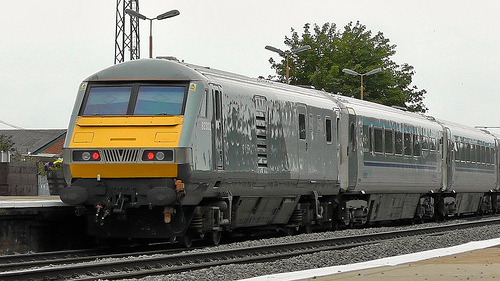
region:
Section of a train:
[53, 50, 221, 252]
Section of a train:
[194, 50, 309, 266]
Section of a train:
[261, 48, 347, 255]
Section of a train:
[272, 47, 362, 245]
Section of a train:
[314, 59, 397, 252]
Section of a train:
[347, 46, 413, 259]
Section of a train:
[392, 86, 452, 248]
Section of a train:
[335, 53, 414, 245]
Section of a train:
[445, 104, 489, 269]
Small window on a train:
[87, 75, 119, 120]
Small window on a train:
[131, 78, 186, 130]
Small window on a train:
[290, 109, 310, 157]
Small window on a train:
[320, 114, 332, 145]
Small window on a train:
[367, 121, 384, 156]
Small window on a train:
[381, 123, 393, 155]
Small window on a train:
[390, 123, 401, 157]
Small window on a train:
[398, 128, 408, 156]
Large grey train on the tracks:
[68, 48, 498, 259]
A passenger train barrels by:
[59, 50, 497, 227]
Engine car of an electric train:
[57, 54, 348, 254]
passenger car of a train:
[330, 68, 456, 235]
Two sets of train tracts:
[3, 208, 495, 270]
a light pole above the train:
[119, 5, 185, 56]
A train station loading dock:
[2, 180, 97, 249]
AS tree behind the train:
[251, 14, 433, 109]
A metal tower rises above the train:
[105, 5, 152, 65]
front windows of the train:
[66, 74, 213, 123]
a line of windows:
[357, 122, 431, 164]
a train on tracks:
[52, 50, 499, 260]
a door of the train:
[291, 99, 312, 189]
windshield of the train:
[78, 80, 190, 116]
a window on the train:
[371, 123, 386, 155]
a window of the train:
[401, 128, 415, 158]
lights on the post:
[262, 40, 312, 59]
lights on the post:
[339, 65, 386, 79]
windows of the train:
[451, 138, 497, 168]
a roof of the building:
[1, 127, 65, 154]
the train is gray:
[154, 54, 362, 216]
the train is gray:
[145, 55, 352, 242]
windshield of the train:
[87, 83, 194, 111]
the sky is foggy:
[235, 24, 248, 31]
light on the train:
[148, 145, 166, 167]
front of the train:
[60, 60, 200, 203]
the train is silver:
[300, 148, 344, 180]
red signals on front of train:
[89, 149, 154, 163]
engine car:
[60, 56, 349, 241]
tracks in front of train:
[3, 234, 211, 275]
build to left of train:
[3, 111, 75, 206]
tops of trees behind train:
[263, 23, 440, 122]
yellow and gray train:
[51, 53, 497, 250]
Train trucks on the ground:
[0, 210, 499, 279]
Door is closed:
[291, 101, 314, 191]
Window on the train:
[322, 113, 334, 145]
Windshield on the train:
[76, 77, 191, 117]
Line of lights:
[123, 5, 386, 99]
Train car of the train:
[326, 81, 448, 232]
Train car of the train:
[437, 115, 499, 220]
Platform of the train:
[1, 190, 59, 211]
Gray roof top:
[1, 126, 67, 157]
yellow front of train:
[75, 66, 192, 228]